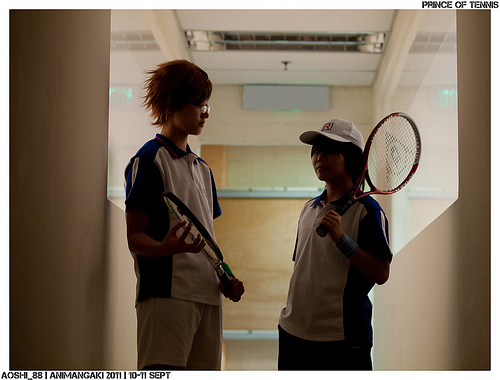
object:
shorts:
[134, 297, 222, 370]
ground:
[410, 119, 445, 165]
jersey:
[121, 133, 223, 308]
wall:
[368, 9, 488, 369]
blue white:
[277, 185, 389, 347]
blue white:
[123, 132, 224, 304]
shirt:
[277, 188, 394, 343]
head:
[148, 60, 209, 135]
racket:
[162, 191, 240, 304]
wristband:
[334, 232, 359, 259]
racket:
[315, 111, 422, 238]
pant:
[276, 323, 374, 371]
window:
[105, 4, 187, 226]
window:
[383, 11, 459, 254]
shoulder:
[345, 192, 385, 229]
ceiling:
[109, 0, 480, 146]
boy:
[276, 118, 393, 371]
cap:
[298, 118, 365, 153]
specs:
[191, 102, 211, 114]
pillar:
[13, 11, 112, 368]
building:
[11, 11, 484, 366]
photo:
[11, 13, 484, 369]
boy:
[123, 59, 245, 369]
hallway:
[106, 11, 485, 363]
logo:
[320, 122, 334, 131]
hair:
[142, 57, 212, 127]